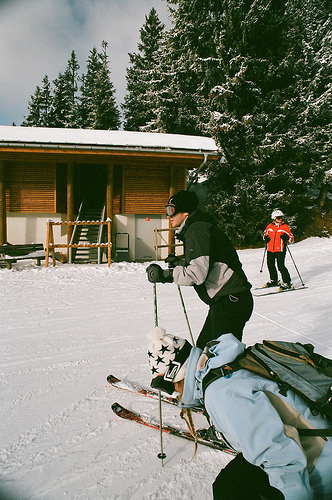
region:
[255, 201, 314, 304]
skier in the snow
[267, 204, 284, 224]
helmet on the skier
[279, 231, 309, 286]
pole in the skier's hand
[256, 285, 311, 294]
ski on the snow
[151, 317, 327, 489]
skier in the snow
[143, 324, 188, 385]
hat on the skier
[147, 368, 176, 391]
goggles on the skier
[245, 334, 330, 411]
backpack on the skier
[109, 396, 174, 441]
ski on the snow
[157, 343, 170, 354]
star on the hat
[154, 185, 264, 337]
man wearing green and gray jacket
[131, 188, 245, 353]
man wearing black hat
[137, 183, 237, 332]
man wearing goggles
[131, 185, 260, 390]
man standing on skiis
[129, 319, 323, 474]
woman wearing light blue jacket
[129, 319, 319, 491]
woman wearing white hat with black stars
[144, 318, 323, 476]
woman wearing gray backpack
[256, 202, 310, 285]
woman wearing red jacket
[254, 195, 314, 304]
woman wearing white helmet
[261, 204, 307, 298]
woman wearing black pants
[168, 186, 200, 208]
a black knit cap on a person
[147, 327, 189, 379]
a white knit cap with black stars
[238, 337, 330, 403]
a grey backpack on a woman's back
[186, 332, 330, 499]
a light blue coat on a person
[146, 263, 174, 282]
a black and grey glove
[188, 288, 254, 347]
black pants on a person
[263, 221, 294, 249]
a red and white coat on a person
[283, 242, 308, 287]
a ski pole in a person's hand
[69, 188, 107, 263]
stairs coming out of a house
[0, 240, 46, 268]
a bench beside a house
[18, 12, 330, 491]
Photo taken during the day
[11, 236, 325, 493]
The ground is white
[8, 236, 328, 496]
Snow covered ground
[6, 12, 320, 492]
Photo taken in the winter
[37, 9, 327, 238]
Evergreen trees with snow on them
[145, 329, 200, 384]
White hat with black stars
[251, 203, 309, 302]
Skier with a red jacket on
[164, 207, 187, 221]
Goggles on the man's face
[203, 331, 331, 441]
Backpack on the woman's back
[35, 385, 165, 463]
Snow on the ground.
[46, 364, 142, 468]
Tracks in the snow.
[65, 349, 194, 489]
Skis in the snow.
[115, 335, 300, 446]
Hat on the skier.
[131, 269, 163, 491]
Pole in the snow.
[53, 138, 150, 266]
Door on the house.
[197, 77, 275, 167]
Snow on the tree.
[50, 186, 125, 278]
Stairs by the cabin.